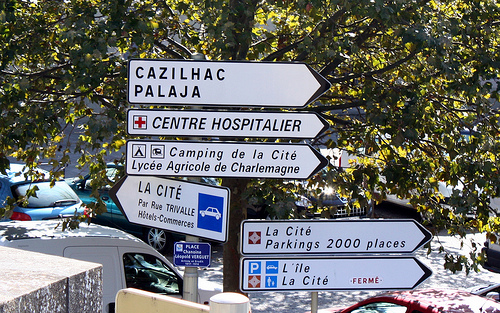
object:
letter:
[136, 66, 145, 78]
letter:
[147, 67, 156, 79]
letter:
[159, 67, 167, 79]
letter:
[172, 67, 176, 79]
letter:
[180, 68, 186, 79]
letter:
[191, 68, 200, 81]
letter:
[157, 85, 164, 97]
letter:
[180, 86, 187, 98]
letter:
[232, 118, 240, 131]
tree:
[0, 0, 499, 295]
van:
[0, 219, 201, 312]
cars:
[63, 162, 223, 253]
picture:
[197, 193, 224, 233]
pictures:
[248, 261, 278, 288]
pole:
[311, 291, 318, 313]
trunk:
[221, 178, 249, 292]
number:
[327, 238, 360, 248]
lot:
[108, 60, 434, 291]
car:
[0, 162, 92, 221]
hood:
[303, 194, 373, 207]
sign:
[240, 219, 433, 257]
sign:
[240, 257, 434, 293]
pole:
[182, 234, 198, 302]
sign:
[108, 175, 230, 244]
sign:
[172, 242, 212, 267]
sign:
[126, 58, 332, 109]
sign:
[127, 109, 330, 140]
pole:
[220, 178, 249, 296]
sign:
[124, 139, 329, 180]